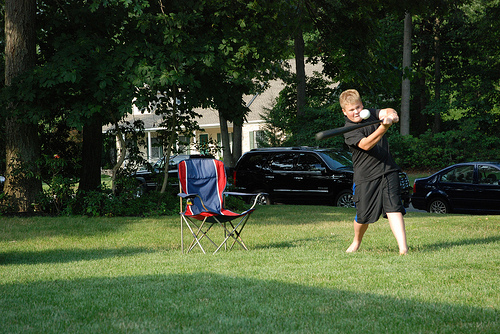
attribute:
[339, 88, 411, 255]
kid — playing, barefoot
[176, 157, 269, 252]
chair — blue, white, red, foldable, empty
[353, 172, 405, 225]
shorts — black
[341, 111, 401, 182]
t-shirt — black, large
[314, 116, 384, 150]
bat — black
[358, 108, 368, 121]
baseball — white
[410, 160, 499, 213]
sedan — blue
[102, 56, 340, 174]
house — white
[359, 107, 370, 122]
ball — white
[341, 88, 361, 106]
hair — blonde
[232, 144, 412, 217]
van — black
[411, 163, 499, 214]
car — parked